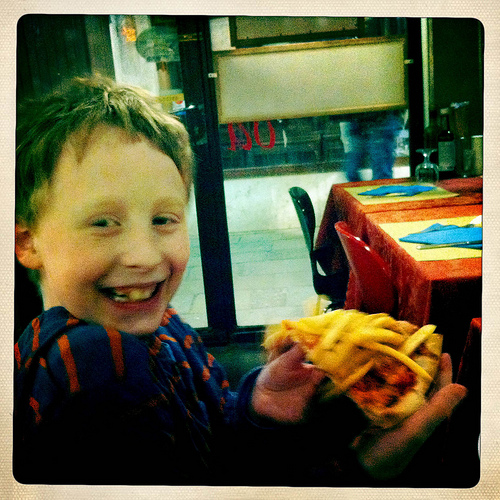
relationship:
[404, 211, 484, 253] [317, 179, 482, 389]
napkin on table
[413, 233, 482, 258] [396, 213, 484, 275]
knife on plate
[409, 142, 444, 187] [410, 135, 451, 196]
glass turned upside down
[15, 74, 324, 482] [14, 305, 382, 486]
boy wearing hoodie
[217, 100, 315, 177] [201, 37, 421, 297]
writing on window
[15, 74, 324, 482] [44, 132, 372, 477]
boy faces camera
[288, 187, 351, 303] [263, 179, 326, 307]
chair with backing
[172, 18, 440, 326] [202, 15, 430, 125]
window with a board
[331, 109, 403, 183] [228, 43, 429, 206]
people conversing outside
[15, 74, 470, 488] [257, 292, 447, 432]
boy holding pizza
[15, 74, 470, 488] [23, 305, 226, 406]
boy wearing hoodie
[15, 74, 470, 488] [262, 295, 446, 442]
boy eating pizza